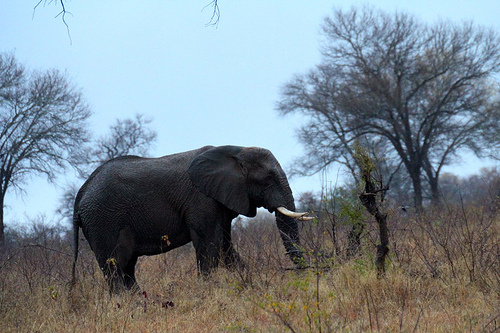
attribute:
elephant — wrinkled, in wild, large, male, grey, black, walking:
[60, 143, 308, 312]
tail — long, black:
[63, 219, 79, 298]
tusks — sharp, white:
[274, 205, 315, 223]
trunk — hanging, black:
[265, 197, 301, 262]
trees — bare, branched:
[278, 8, 497, 227]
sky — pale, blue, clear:
[10, 8, 297, 145]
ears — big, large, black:
[189, 142, 251, 213]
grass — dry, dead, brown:
[12, 274, 493, 325]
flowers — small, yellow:
[234, 271, 327, 330]